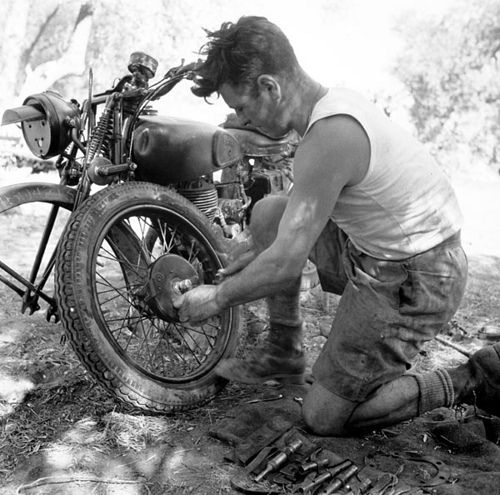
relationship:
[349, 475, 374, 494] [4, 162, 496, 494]
tool on ground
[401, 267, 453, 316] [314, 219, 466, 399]
pocket on shorts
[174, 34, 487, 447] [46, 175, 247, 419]
man holding tire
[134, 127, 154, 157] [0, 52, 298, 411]
dent in bike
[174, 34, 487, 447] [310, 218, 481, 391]
man wearing shorts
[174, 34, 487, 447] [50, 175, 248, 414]
man fixing tire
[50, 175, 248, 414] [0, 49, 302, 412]
tire on bike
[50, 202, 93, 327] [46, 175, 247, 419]
treads on tire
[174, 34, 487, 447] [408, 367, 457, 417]
man wearing sock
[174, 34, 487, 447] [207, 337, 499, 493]
man kneeling on blanket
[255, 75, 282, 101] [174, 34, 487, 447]
ear of man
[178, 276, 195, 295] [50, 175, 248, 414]
bolt in middle of tire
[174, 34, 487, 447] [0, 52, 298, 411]
man repairing bike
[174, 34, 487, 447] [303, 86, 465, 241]
man wearing shirt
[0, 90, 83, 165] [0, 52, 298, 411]
bike headlight on bike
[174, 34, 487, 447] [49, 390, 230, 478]
man in shade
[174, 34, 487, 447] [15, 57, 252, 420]
man repairing bike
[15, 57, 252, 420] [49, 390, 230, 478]
bike in shade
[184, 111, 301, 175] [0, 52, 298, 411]
seat of bike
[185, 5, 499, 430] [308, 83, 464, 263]
man wearing tank top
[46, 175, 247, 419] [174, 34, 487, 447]
tire in front of man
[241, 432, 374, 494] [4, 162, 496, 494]
tool on ground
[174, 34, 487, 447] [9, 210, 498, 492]
man kneeling on ground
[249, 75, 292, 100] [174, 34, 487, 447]
ear of man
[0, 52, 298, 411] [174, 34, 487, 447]
bike behind man